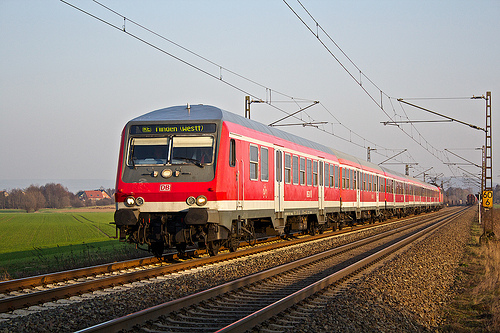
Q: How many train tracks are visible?
A: Two.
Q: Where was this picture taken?
A: Train tracks.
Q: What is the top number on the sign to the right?
A: 60.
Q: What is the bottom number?
A: 6.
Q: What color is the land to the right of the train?
A: Green.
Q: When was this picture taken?
A: Day time.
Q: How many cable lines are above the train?
A: Four.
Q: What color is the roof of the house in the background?
A: Red.